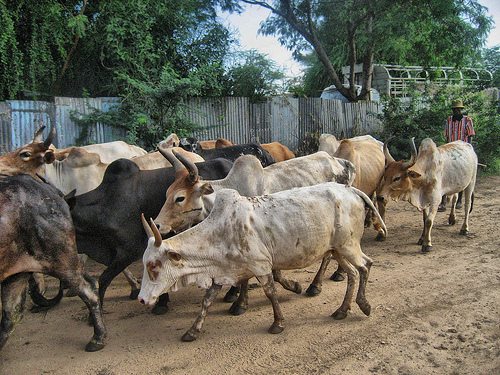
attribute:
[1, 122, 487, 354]
group — cows, walking, male, female, looking for food, being driven, out, enjoying day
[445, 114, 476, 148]
shirt — striped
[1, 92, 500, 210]
fence — metal, white